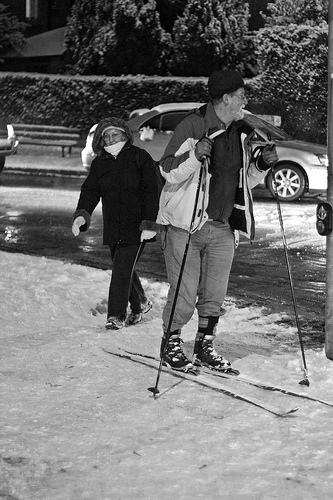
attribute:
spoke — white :
[284, 167, 291, 178]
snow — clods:
[0, 253, 328, 499]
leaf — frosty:
[307, 71, 313, 83]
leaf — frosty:
[267, 33, 279, 45]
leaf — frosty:
[253, 98, 258, 101]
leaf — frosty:
[310, 32, 324, 45]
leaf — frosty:
[264, 15, 275, 25]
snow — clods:
[259, 307, 299, 349]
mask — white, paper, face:
[102, 143, 125, 159]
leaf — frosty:
[293, 70, 306, 85]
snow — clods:
[61, 340, 140, 414]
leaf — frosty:
[289, 93, 295, 97]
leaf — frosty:
[287, 80, 316, 97]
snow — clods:
[2, 267, 85, 398]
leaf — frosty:
[288, 100, 307, 110]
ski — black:
[100, 345, 297, 416]